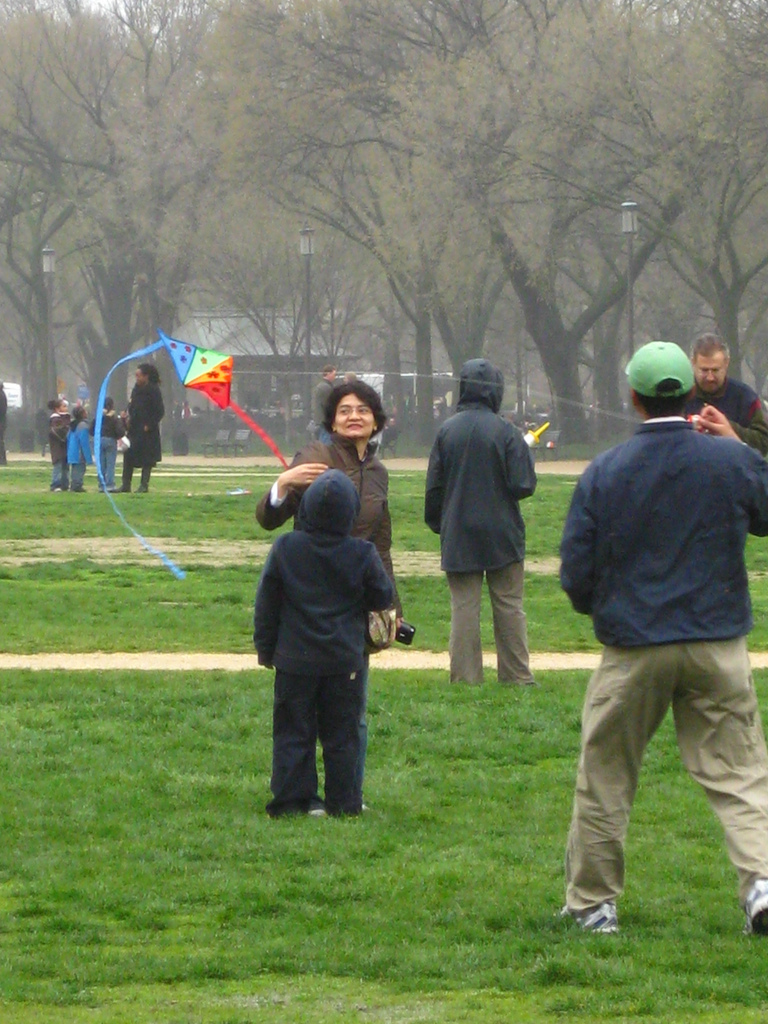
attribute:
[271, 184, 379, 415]
light — tall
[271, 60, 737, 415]
park — street light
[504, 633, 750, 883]
pant — tan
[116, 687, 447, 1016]
grass — green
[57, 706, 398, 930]
grass — green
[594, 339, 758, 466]
hat — green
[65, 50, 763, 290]
trees — many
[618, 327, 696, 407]
green cap — baseball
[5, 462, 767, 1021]
grass field — dirt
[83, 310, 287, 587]
kite — multi colored